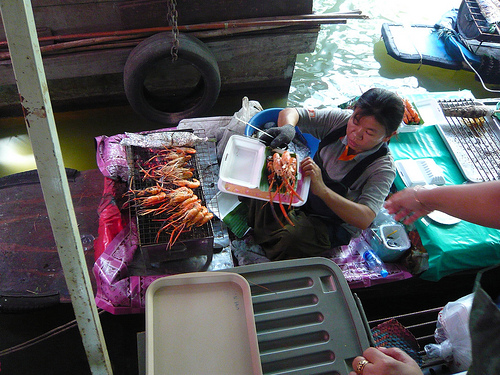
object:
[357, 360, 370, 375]
band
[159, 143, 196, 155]
shrimp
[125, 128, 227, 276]
grill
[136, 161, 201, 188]
shrimp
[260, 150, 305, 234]
seafood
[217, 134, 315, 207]
container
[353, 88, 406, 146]
dark hair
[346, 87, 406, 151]
head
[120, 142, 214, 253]
seafood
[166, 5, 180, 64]
chain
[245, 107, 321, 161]
bucket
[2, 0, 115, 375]
support pole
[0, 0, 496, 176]
river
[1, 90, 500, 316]
boat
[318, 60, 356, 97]
water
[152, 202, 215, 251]
shrimp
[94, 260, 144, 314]
bandanna print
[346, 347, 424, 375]
hand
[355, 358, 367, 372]
ring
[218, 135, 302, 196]
styrofoam container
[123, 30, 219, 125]
old tire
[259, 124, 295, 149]
glove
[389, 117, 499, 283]
tarp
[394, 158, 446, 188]
box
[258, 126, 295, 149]
hand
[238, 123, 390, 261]
apron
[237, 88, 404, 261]
woman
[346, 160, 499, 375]
customer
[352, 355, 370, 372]
finger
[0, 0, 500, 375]
dock